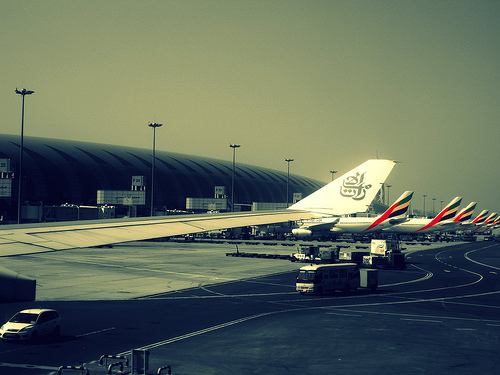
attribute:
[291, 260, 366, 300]
bus — large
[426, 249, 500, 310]
lines — white, curvy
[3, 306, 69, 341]
car — white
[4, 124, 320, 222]
airport — dark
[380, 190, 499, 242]
tails — striped, colorful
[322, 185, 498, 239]
planes — white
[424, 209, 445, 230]
stripe — red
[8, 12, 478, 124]
sky — overcast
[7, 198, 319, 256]
wing — white, thin, bent